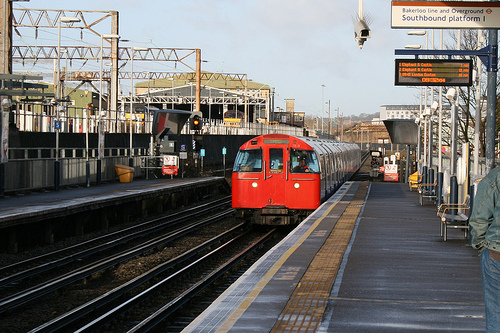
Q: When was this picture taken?
A: During the day.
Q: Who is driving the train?
A: The conductor.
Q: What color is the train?
A: Red.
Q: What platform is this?
A: Southbound platform I.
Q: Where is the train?
A: On the tracks.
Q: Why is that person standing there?
A: They are waiting for the train.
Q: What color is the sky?
A: Blue.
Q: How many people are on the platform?
A: One.